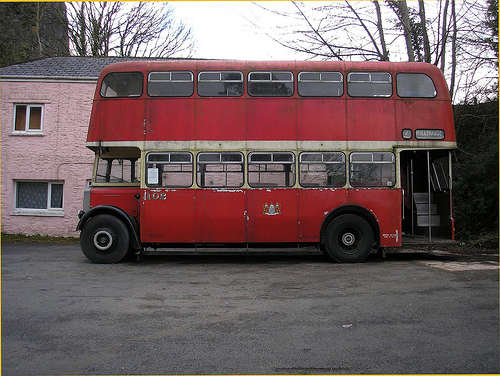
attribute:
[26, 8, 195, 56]
trees — behind